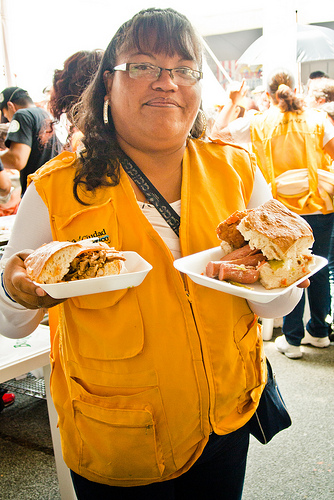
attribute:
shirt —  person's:
[17, 108, 47, 145]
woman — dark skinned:
[7, 10, 302, 490]